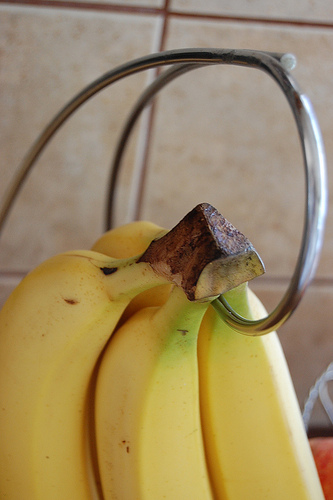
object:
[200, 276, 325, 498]
banana